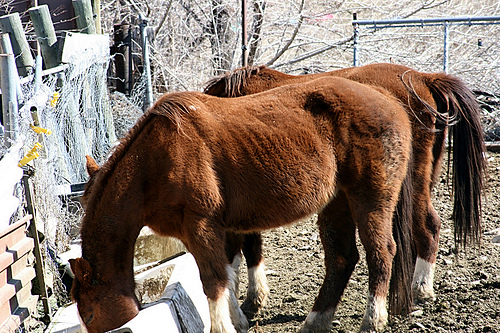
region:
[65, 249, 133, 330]
head of a horse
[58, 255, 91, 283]
ear of a horse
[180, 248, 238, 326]
leg of a horse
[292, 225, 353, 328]
leg of a horse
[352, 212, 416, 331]
leg of a horse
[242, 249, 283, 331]
leg of a horse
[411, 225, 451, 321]
leg of a horse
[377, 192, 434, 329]
tail of a horse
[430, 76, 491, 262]
tail of a horse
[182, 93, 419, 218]
body of a horse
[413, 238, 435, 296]
foot of the horse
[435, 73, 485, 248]
tail of the horse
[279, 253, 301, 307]
rocks on the ground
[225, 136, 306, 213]
fur on the horse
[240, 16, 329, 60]
branches on the tree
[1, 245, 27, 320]
bricks on the wall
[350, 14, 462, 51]
metal fencing near trees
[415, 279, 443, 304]
hoof of the horse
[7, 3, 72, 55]
pipe above the fence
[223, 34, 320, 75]
the trees are dead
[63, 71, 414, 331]
A horse eating food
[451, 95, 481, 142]
Part of the tail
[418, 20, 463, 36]
Part of the fence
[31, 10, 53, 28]
Part of the wood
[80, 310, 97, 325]
The left eye of the horse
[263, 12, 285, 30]
Part of the tree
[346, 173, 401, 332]
The back leg of the horse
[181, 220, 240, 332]
The front leg of the horse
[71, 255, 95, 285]
The left ear of the horse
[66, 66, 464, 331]
horse drinking water from cowpots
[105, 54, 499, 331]
two horse standing near the cowpot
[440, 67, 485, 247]
tail of the horse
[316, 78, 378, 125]
point of hip in the horse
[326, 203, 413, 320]
legs of the horse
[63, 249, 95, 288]
ear of the horse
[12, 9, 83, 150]
wood fencing with steel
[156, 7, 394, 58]
trees with branches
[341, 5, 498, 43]
metal post near the tree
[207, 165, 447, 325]
horse standing in the dirt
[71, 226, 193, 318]
the head of a horse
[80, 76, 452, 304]
a horse drinking water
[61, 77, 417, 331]
the horse is brown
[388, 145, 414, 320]
the tail is brown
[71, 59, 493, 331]
the horses are standing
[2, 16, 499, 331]
the chain link fence is gray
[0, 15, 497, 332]
the chain link fence around the horses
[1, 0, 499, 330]
the bare trees behind the horses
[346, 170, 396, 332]
the leg is brown and white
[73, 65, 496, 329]
two horses grazing together